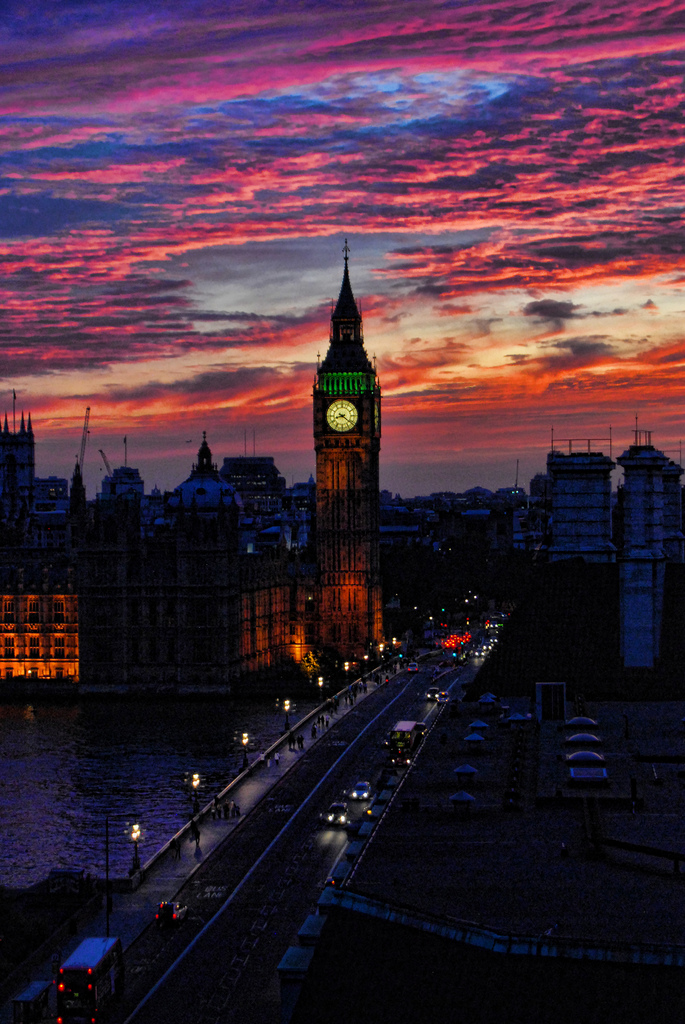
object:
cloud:
[474, 279, 675, 340]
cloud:
[30, 292, 309, 401]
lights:
[319, 369, 382, 401]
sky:
[3, 0, 684, 378]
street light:
[181, 767, 208, 821]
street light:
[233, 723, 257, 777]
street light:
[271, 695, 301, 731]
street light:
[307, 673, 333, 708]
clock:
[325, 395, 366, 452]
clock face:
[322, 397, 358, 433]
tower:
[308, 235, 387, 665]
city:
[2, 235, 685, 730]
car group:
[438, 629, 472, 651]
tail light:
[443, 643, 450, 649]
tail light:
[449, 643, 455, 648]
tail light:
[463, 630, 470, 636]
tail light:
[463, 635, 467, 641]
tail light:
[447, 632, 454, 638]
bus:
[54, 934, 127, 1022]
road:
[89, 671, 341, 1023]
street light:
[128, 818, 145, 879]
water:
[4, 701, 173, 852]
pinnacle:
[340, 235, 352, 259]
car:
[150, 895, 188, 927]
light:
[153, 912, 160, 918]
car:
[564, 747, 609, 780]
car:
[560, 728, 608, 753]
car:
[561, 712, 600, 734]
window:
[44, 635, 68, 662]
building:
[0, 418, 83, 679]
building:
[300, 236, 401, 698]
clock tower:
[308, 236, 390, 674]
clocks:
[319, 392, 386, 449]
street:
[37, 603, 462, 1016]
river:
[3, 684, 164, 858]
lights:
[116, 592, 480, 844]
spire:
[333, 219, 356, 288]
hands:
[341, 411, 357, 430]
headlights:
[320, 810, 352, 832]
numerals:
[322, 402, 363, 438]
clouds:
[4, 6, 682, 433]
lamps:
[110, 588, 387, 852]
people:
[212, 785, 251, 835]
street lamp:
[176, 769, 210, 824]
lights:
[46, 966, 103, 1024]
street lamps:
[112, 807, 153, 881]